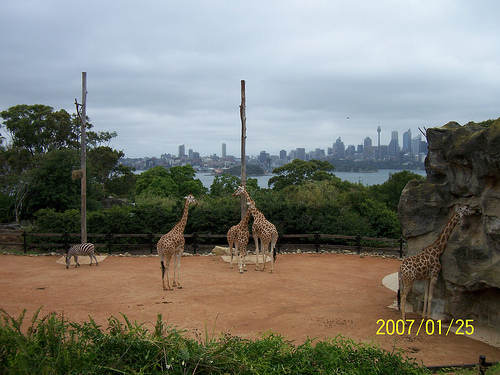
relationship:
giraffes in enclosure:
[167, 191, 281, 265] [11, 217, 494, 373]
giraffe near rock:
[380, 194, 499, 325] [394, 121, 498, 319]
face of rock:
[389, 114, 497, 349] [394, 121, 498, 319]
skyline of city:
[282, 115, 430, 169] [144, 138, 438, 166]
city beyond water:
[144, 138, 438, 166] [201, 167, 414, 189]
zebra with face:
[62, 235, 100, 271] [389, 114, 497, 349]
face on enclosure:
[57, 251, 72, 263] [0, 232, 490, 372]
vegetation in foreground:
[8, 319, 389, 374] [16, 311, 493, 362]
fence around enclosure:
[11, 228, 394, 257] [11, 217, 494, 373]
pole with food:
[237, 80, 255, 250] [224, 244, 282, 266]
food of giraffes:
[224, 244, 282, 266] [167, 191, 281, 265]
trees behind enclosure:
[24, 153, 424, 243] [11, 217, 494, 373]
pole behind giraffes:
[237, 80, 255, 250] [167, 191, 281, 265]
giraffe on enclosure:
[380, 194, 499, 325] [0, 232, 490, 372]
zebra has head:
[62, 235, 100, 271] [59, 259, 72, 270]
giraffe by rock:
[380, 194, 499, 325] [394, 121, 498, 319]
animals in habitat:
[58, 197, 457, 318] [7, 8, 494, 372]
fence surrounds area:
[11, 228, 394, 257] [7, 248, 483, 372]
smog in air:
[19, 14, 484, 167] [13, 8, 485, 166]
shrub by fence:
[291, 185, 349, 243] [11, 228, 394, 257]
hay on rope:
[69, 167, 89, 186] [80, 78, 87, 165]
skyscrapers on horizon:
[291, 131, 430, 168] [14, 110, 495, 175]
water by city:
[201, 167, 414, 189] [144, 138, 438, 166]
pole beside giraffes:
[237, 80, 255, 250] [167, 191, 281, 265]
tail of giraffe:
[392, 288, 403, 310] [380, 194, 499, 325]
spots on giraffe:
[407, 250, 433, 274] [380, 194, 499, 325]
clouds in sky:
[28, 10, 461, 82] [4, 8, 496, 140]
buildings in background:
[125, 137, 442, 170] [3, 4, 481, 157]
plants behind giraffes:
[6, 162, 400, 231] [167, 191, 281, 265]